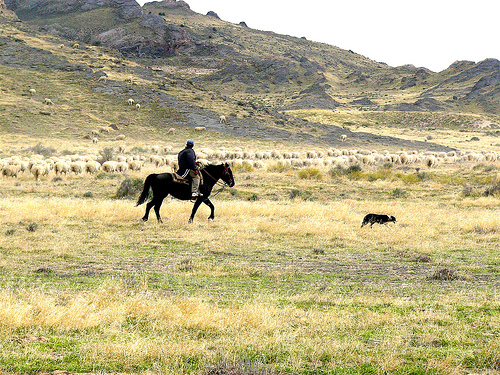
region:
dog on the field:
[346, 205, 403, 237]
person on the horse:
[175, 135, 199, 198]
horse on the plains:
[136, 162, 253, 224]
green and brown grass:
[8, 183, 483, 371]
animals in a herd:
[0, 144, 468, 177]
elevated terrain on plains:
[6, 4, 454, 135]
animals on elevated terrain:
[53, 45, 245, 122]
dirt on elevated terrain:
[196, 113, 226, 130]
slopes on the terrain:
[398, 54, 498, 104]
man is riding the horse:
[124, 127, 256, 234]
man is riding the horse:
[127, 122, 247, 222]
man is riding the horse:
[130, 124, 250, 239]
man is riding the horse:
[114, 127, 244, 232]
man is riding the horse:
[118, 113, 236, 222]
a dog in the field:
[340, 199, 402, 236]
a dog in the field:
[351, 207, 392, 235]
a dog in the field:
[353, 198, 402, 242]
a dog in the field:
[350, 192, 404, 252]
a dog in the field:
[350, 193, 417, 246]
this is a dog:
[355, 200, 415, 236]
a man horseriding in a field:
[105, 125, 270, 230]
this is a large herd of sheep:
[10, 140, 496, 171]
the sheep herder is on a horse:
[115, 116, 275, 266]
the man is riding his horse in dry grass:
[90, 95, 275, 230]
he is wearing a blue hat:
[175, 125, 195, 150]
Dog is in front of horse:
[360, 211, 395, 227]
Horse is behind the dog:
[135, 135, 235, 225]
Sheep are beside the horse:
[0, 145, 497, 175]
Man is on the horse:
[175, 135, 200, 197]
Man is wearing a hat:
[176, 136, 201, 197]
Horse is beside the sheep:
[133, 162, 237, 226]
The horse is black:
[134, 162, 236, 227]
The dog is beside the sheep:
[359, 211, 400, 227]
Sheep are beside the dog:
[0, 150, 498, 174]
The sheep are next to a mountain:
[0, 150, 498, 175]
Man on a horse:
[131, 137, 247, 224]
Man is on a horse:
[130, 132, 241, 223]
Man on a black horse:
[132, 135, 238, 227]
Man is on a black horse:
[131, 135, 246, 233]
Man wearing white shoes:
[187, 187, 212, 200]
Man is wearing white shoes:
[188, 189, 204, 199]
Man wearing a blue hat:
[180, 137, 200, 149]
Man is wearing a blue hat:
[182, 134, 199, 148]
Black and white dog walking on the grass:
[358, 210, 400, 228]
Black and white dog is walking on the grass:
[355, 210, 406, 235]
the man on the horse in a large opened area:
[1, 0, 499, 374]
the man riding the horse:
[133, 138, 237, 225]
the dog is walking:
[358, 213, 397, 232]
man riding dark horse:
[136, 129, 235, 227]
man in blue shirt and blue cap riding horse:
[176, 140, 206, 198]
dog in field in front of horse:
[361, 213, 400, 230]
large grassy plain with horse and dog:
[3, 162, 498, 371]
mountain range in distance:
[10, 0, 495, 146]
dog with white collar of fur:
[361, 211, 399, 228]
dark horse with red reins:
[133, 158, 241, 221]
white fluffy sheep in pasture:
[6, 139, 488, 181]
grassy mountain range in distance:
[1, 3, 498, 139]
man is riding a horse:
[136, 138, 234, 223]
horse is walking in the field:
[129, 164, 243, 239]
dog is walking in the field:
[351, 204, 408, 236]